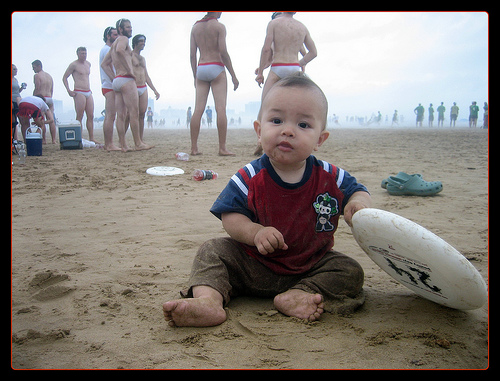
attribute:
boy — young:
[157, 74, 370, 326]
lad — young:
[161, 75, 376, 332]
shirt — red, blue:
[211, 153, 371, 271]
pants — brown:
[178, 239, 366, 304]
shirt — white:
[20, 96, 47, 112]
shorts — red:
[16, 103, 41, 118]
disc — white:
[144, 163, 184, 175]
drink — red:
[194, 173, 217, 180]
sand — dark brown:
[11, 125, 489, 365]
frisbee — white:
[348, 205, 489, 310]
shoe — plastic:
[384, 170, 443, 195]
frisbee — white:
[144, 163, 184, 177]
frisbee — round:
[348, 206, 489, 334]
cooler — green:
[58, 119, 85, 156]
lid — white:
[57, 123, 81, 127]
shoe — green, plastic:
[391, 181, 438, 195]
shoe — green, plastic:
[381, 173, 393, 190]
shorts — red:
[15, 103, 45, 123]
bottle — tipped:
[191, 170, 220, 183]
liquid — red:
[195, 169, 217, 181]